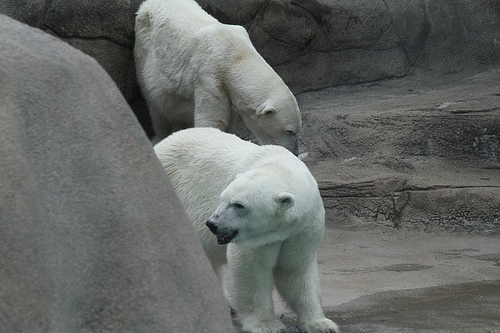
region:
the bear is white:
[203, 171, 302, 312]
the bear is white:
[220, 229, 290, 329]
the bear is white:
[247, 141, 312, 271]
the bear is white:
[211, 199, 261, 261]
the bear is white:
[278, 276, 303, 314]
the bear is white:
[178, 215, 270, 329]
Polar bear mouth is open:
[209, 224, 240, 247]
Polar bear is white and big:
[154, 131, 334, 331]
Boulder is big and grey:
[5, 22, 202, 329]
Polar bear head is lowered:
[238, 70, 315, 151]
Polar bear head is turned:
[191, 177, 304, 257]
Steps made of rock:
[316, 115, 493, 205]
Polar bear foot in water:
[296, 277, 495, 331]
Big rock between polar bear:
[278, 6, 492, 76]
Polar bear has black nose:
[204, 216, 217, 230]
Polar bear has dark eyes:
[226, 197, 248, 215]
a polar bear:
[191, 147, 311, 331]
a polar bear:
[193, 176, 260, 316]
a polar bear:
[228, 184, 284, 326]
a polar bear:
[243, 171, 307, 319]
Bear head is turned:
[194, 167, 300, 264]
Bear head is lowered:
[226, 68, 320, 151]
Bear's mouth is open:
[199, 210, 244, 247]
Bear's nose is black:
[201, 215, 218, 232]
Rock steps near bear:
[310, 117, 499, 221]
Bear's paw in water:
[286, 305, 448, 331]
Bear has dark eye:
[226, 200, 252, 215]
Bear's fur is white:
[163, 135, 295, 220]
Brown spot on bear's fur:
[221, 39, 253, 79]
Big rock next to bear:
[8, 72, 204, 328]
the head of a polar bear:
[201, 162, 306, 252]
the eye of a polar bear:
[226, 200, 246, 211]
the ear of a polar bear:
[270, 185, 301, 212]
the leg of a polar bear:
[271, 225, 326, 320]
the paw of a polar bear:
[290, 306, 341, 327]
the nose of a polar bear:
[202, 213, 218, 230]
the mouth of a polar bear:
[211, 222, 243, 248]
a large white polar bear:
[145, 124, 354, 331]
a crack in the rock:
[390, 187, 412, 224]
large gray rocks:
[0, 0, 499, 330]